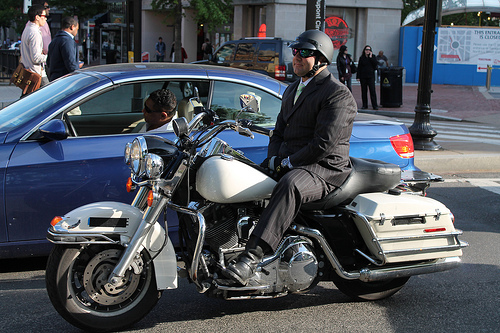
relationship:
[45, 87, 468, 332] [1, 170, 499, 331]
motorcycle on top of road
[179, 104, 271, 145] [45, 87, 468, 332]
handlebars of motorcycle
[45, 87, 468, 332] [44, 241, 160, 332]
motorcycle has front tire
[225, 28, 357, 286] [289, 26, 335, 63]
man wearing helmet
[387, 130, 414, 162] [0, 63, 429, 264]
brake light on back of car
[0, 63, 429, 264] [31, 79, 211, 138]
car has open window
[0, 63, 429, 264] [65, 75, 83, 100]
car has rearview mirror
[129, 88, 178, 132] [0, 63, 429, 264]
man sitting in car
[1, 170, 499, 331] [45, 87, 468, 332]
road beneath motorcycle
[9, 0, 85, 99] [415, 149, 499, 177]
people walking on sidewalk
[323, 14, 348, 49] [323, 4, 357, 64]
neon sign in window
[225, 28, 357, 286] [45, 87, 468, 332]
man riding motorcycle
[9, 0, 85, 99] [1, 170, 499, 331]
people walking down road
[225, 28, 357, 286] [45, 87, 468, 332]
man sitting on motorcycle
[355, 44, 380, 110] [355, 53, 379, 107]
woman wearing black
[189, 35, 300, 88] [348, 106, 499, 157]
suv parked on road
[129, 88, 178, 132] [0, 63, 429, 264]
man driving car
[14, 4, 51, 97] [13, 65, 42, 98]
man carrying satchel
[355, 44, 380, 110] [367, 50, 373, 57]
woman talking on cellphone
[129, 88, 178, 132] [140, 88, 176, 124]
man has head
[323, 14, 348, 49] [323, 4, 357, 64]
neon sign hanging on window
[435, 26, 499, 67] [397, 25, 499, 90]
map attached to wall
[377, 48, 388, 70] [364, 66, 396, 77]
man sitting on bench